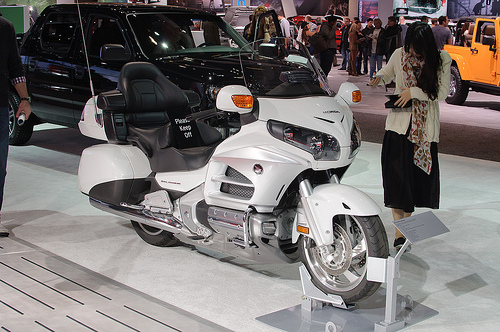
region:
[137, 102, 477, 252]
the motorcycle is white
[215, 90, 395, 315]
the motorcycle is white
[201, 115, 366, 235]
the motorcycle is white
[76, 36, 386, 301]
a white street motorcycle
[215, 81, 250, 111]
the amber turning signal light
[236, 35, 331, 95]
the motorcycles tinted windshield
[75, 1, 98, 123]
the motorcycle radio antenna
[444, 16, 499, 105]
a school bus yellow truck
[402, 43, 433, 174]
a ladies floral scarf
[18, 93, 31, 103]
a mans wrist watch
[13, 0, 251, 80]
a black pick up truck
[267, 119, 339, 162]
the motorcycles right side headlight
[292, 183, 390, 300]
the front fender and wheel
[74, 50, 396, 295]
white motorcycle on display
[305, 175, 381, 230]
fender on bike wheel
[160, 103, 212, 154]
sign on bike seat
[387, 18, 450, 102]
woman with long hair looking down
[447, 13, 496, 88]
side of orange vehicle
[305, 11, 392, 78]
crowd of people standing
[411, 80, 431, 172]
long scarf on woman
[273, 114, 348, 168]
headlights on front of bike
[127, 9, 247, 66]
windshield of parked vehicle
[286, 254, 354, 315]
black tire in stand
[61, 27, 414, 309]
A large white motorcycle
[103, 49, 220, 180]
The seat of a motorcycle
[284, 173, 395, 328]
The front wheel of a motorcycle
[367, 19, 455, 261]
A woman in a black skirt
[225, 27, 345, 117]
The windshield of a motorcycle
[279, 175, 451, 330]
A wheel support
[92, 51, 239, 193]
Black leather upholstery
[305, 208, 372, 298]
The spokes of a motorcycle wheel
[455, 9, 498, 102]
The side of an orange truck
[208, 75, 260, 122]
A signal light on a motorcycle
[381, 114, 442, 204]
Woman in black dress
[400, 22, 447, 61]
Woman with black hair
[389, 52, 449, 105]
Woman wearing white shirt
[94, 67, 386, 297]
Black and white motorcycle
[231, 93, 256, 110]
Yellow light on motorcycle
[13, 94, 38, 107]
Man wearing wrist watch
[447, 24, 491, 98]
Yellow jeep parked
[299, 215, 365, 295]
Chrome wheels on a motorcycle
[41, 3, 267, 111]
Black jeep parked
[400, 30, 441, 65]
Woman looking down